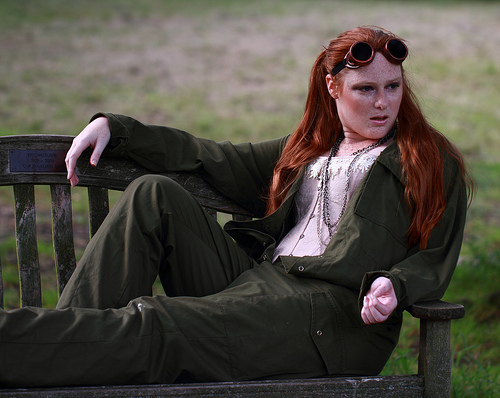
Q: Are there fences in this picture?
A: No, there are no fences.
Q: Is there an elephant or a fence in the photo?
A: No, there are no fences or elephants.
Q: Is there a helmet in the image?
A: No, there are no helmets.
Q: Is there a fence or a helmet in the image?
A: No, there are no helmets or fences.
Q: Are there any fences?
A: No, there are no fences.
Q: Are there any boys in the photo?
A: No, there are no boys.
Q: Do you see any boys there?
A: No, there are no boys.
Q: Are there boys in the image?
A: No, there are no boys.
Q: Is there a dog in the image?
A: No, there are no dogs.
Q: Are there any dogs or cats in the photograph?
A: No, there are no dogs or cats.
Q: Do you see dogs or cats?
A: No, there are no dogs or cats.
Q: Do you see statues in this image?
A: No, there are no statues.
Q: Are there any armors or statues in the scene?
A: No, there are no statues or armors.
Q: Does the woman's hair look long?
A: Yes, the hair is long.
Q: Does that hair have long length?
A: Yes, the hair is long.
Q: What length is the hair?
A: The hair is long.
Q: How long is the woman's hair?
A: The hair is long.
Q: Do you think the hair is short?
A: No, the hair is long.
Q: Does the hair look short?
A: No, the hair is long.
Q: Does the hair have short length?
A: No, the hair is long.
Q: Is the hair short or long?
A: The hair is long.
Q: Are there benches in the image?
A: Yes, there is a bench.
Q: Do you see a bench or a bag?
A: Yes, there is a bench.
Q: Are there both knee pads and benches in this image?
A: No, there is a bench but no knee pads.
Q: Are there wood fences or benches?
A: Yes, there is a wood bench.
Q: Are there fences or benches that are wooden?
A: Yes, the bench is wooden.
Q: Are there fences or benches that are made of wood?
A: Yes, the bench is made of wood.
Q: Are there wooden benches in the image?
A: Yes, there is a wood bench.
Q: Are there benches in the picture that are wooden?
A: Yes, there is a bench that is wooden.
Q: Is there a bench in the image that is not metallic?
A: Yes, there is a wooden bench.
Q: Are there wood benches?
A: Yes, there is a bench that is made of wood.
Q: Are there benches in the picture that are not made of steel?
A: Yes, there is a bench that is made of wood.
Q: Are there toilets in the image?
A: No, there are no toilets.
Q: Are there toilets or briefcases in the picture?
A: No, there are no toilets or briefcases.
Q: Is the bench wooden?
A: Yes, the bench is wooden.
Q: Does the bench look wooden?
A: Yes, the bench is wooden.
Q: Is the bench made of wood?
A: Yes, the bench is made of wood.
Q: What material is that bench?
A: The bench is made of wood.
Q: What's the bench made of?
A: The bench is made of wood.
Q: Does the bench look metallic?
A: No, the bench is wooden.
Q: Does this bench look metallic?
A: No, the bench is wooden.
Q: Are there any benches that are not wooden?
A: No, there is a bench but it is wooden.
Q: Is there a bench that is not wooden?
A: No, there is a bench but it is wooden.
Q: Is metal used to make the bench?
A: No, the bench is made of wood.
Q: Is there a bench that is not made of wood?
A: No, there is a bench but it is made of wood.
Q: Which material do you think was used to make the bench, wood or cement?
A: The bench is made of wood.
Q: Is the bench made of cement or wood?
A: The bench is made of wood.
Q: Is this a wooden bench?
A: Yes, this is a wooden bench.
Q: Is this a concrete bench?
A: No, this is a wooden bench.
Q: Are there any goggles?
A: Yes, there are goggles.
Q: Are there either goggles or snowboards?
A: Yes, there are goggles.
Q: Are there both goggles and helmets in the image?
A: No, there are goggles but no helmets.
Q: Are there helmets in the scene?
A: No, there are no helmets.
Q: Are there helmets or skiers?
A: No, there are no helmets or skiers.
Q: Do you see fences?
A: No, there are no fences.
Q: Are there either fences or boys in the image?
A: No, there are no fences or boys.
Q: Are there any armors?
A: No, there are no armors.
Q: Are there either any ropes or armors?
A: No, there are no armors or ropes.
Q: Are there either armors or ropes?
A: No, there are no armors or ropes.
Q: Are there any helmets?
A: No, there are no helmets.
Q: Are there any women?
A: Yes, there is a woman.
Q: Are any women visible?
A: Yes, there is a woman.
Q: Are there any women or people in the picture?
A: Yes, there is a woman.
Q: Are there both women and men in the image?
A: No, there is a woman but no men.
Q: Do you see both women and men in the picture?
A: No, there is a woman but no men.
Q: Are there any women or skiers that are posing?
A: Yes, the woman is posing.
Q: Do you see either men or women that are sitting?
A: Yes, the woman is sitting.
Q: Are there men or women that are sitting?
A: Yes, the woman is sitting.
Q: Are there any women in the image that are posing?
A: Yes, there is a woman that is posing.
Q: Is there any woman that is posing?
A: Yes, there is a woman that is posing.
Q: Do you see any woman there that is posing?
A: Yes, there is a woman that is posing.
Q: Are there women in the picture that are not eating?
A: Yes, there is a woman that is posing.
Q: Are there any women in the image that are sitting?
A: Yes, there is a woman that is sitting.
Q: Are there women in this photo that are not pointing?
A: Yes, there is a woman that is sitting.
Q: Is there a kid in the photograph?
A: No, there are no children.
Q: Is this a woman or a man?
A: This is a woman.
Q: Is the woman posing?
A: Yes, the woman is posing.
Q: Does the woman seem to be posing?
A: Yes, the woman is posing.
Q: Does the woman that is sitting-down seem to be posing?
A: Yes, the woman is posing.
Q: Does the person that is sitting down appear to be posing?
A: Yes, the woman is posing.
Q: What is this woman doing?
A: The woman is posing.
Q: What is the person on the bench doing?
A: The woman is posing.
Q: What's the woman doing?
A: The woman is posing.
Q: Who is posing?
A: The woman is posing.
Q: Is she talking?
A: No, the woman is posing.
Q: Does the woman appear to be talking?
A: No, the woman is posing.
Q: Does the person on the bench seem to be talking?
A: No, the woman is posing.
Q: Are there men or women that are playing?
A: No, there is a woman but she is posing.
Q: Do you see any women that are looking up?
A: No, there is a woman but she is posing.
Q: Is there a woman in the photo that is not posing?
A: No, there is a woman but she is posing.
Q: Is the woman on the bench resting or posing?
A: The woman is posing.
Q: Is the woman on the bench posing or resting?
A: The woman is posing.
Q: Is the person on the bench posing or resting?
A: The woman is posing.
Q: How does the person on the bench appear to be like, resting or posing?
A: The woman is posing.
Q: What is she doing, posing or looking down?
A: The woman is posing.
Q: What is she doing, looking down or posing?
A: The woman is posing.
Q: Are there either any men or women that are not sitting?
A: No, there is a woman but she is sitting.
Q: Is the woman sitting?
A: Yes, the woman is sitting.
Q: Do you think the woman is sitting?
A: Yes, the woman is sitting.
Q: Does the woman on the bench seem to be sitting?
A: Yes, the woman is sitting.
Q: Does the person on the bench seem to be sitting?
A: Yes, the woman is sitting.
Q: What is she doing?
A: The woman is sitting.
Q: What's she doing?
A: The woman is sitting.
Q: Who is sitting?
A: The woman is sitting.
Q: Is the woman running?
A: No, the woman is sitting.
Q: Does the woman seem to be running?
A: No, the woman is sitting.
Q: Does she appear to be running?
A: No, the woman is sitting.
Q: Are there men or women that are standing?
A: No, there is a woman but she is sitting.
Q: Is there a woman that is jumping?
A: No, there is a woman but she is sitting.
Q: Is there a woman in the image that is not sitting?
A: No, there is a woman but she is sitting.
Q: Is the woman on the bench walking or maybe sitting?
A: The woman is sitting.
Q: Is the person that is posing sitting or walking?
A: The woman is sitting.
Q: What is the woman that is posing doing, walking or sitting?
A: The woman is sitting.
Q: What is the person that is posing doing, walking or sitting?
A: The woman is sitting.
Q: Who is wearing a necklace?
A: The woman is wearing a necklace.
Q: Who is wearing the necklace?
A: The woman is wearing a necklace.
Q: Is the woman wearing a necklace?
A: Yes, the woman is wearing a necklace.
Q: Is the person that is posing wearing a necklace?
A: Yes, the woman is wearing a necklace.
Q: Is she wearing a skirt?
A: No, the woman is wearing a necklace.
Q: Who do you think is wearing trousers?
A: The woman is wearing trousers.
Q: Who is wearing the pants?
A: The woman is wearing trousers.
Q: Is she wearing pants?
A: Yes, the woman is wearing pants.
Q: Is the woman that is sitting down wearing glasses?
A: No, the woman is wearing pants.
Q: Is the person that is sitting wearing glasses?
A: No, the woman is wearing pants.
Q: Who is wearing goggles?
A: The woman is wearing goggles.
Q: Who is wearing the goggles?
A: The woman is wearing goggles.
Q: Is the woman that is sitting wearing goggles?
A: Yes, the woman is wearing goggles.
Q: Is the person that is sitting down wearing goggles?
A: Yes, the woman is wearing goggles.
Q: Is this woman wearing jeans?
A: No, the woman is wearing goggles.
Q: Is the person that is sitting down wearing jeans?
A: No, the woman is wearing goggles.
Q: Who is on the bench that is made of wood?
A: The woman is on the bench.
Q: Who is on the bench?
A: The woman is on the bench.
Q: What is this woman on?
A: The woman is on the bench.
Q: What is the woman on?
A: The woman is on the bench.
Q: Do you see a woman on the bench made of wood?
A: Yes, there is a woman on the bench.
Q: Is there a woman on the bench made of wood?
A: Yes, there is a woman on the bench.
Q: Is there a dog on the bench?
A: No, there is a woman on the bench.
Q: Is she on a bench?
A: Yes, the woman is on a bench.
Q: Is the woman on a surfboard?
A: No, the woman is on a bench.